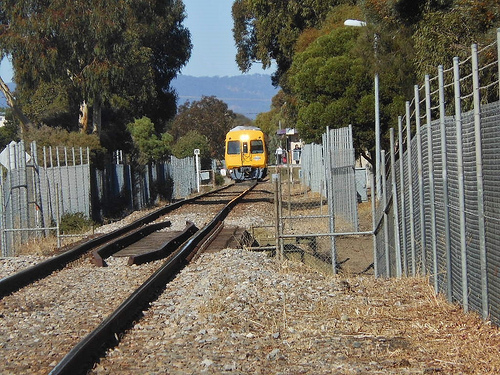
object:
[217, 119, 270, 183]
bus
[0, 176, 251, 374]
tracks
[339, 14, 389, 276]
light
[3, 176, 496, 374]
street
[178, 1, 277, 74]
sky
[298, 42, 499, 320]
fence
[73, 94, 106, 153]
trunk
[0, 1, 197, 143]
trees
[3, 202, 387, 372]
rocks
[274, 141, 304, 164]
people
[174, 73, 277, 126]
hill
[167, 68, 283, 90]
distance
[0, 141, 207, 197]
fence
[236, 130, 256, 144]
white light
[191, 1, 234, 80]
clouds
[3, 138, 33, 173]
diamond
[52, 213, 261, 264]
bridge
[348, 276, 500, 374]
grass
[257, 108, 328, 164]
distance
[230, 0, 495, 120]
trees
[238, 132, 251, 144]
light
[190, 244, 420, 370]
rocks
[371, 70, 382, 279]
pole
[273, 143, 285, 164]
man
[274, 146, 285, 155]
white shirt